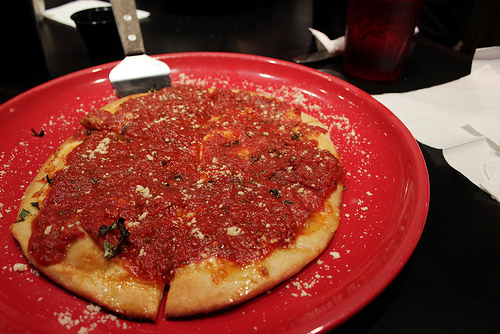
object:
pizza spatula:
[106, 0, 170, 97]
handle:
[109, 0, 148, 57]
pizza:
[6, 84, 346, 324]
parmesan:
[327, 249, 339, 260]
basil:
[101, 213, 132, 268]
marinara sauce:
[40, 89, 344, 287]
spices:
[186, 221, 191, 226]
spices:
[136, 184, 144, 193]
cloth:
[370, 46, 499, 204]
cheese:
[224, 221, 248, 240]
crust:
[12, 228, 152, 334]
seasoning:
[155, 150, 171, 166]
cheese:
[184, 214, 203, 238]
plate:
[3, 50, 430, 334]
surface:
[9, 86, 345, 322]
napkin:
[367, 46, 500, 201]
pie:
[11, 83, 343, 325]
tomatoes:
[25, 212, 81, 267]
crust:
[7, 209, 140, 309]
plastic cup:
[335, 1, 422, 82]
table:
[6, 1, 500, 334]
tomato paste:
[24, 86, 342, 291]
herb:
[94, 214, 131, 260]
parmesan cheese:
[87, 305, 99, 318]